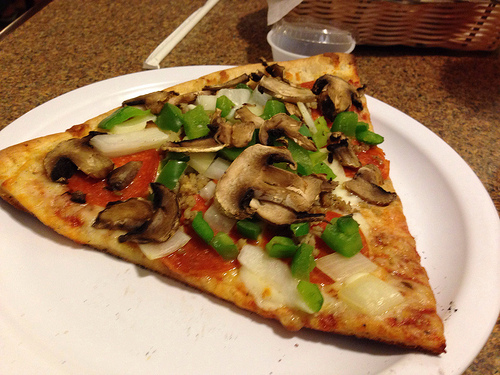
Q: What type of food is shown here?
A: Pizza.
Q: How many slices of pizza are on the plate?
A: One.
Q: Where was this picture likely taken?
A: A restaurant.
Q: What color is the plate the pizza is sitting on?
A: White.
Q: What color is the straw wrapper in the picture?
A: White.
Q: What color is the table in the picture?
A: Brown.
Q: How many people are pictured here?
A: Zero.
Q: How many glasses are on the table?
A: Zero.